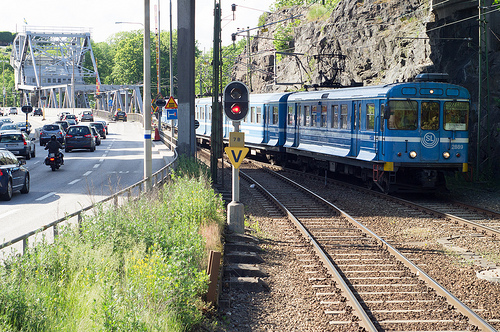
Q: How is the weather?
A: It is clear.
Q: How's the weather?
A: It is clear.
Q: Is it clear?
A: Yes, it is clear.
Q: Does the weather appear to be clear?
A: Yes, it is clear.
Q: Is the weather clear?
A: Yes, it is clear.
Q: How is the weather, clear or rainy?
A: It is clear.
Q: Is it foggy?
A: No, it is clear.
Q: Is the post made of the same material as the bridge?
A: No, the post is made of wood and the bridge is made of metal.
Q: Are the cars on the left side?
A: Yes, the cars are on the left of the image.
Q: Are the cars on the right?
A: No, the cars are on the left of the image.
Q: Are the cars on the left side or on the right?
A: The cars are on the left of the image.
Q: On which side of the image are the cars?
A: The cars are on the left of the image.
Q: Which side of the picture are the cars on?
A: The cars are on the left of the image.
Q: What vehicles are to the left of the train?
A: The vehicles are cars.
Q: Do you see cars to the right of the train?
A: No, the cars are to the left of the train.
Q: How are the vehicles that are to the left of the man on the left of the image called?
A: The vehicles are cars.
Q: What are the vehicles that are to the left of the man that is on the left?
A: The vehicles are cars.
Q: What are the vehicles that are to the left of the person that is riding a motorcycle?
A: The vehicles are cars.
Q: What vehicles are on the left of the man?
A: The vehicles are cars.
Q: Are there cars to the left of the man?
A: Yes, there are cars to the left of the man.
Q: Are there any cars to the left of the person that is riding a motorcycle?
A: Yes, there are cars to the left of the man.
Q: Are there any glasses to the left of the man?
A: No, there are cars to the left of the man.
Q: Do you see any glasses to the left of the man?
A: No, there are cars to the left of the man.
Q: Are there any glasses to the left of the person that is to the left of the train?
A: No, there are cars to the left of the man.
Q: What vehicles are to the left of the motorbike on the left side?
A: The vehicles are cars.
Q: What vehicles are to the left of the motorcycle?
A: The vehicles are cars.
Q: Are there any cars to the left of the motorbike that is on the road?
A: Yes, there are cars to the left of the motorbike.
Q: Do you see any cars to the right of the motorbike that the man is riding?
A: No, the cars are to the left of the motorbike.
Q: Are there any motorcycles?
A: Yes, there is a motorcycle.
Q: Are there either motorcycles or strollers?
A: Yes, there is a motorcycle.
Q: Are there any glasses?
A: No, there are no glasses.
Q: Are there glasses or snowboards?
A: No, there are no glasses or snowboards.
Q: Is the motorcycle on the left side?
A: Yes, the motorcycle is on the left of the image.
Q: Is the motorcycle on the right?
A: No, the motorcycle is on the left of the image.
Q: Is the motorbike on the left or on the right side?
A: The motorbike is on the left of the image.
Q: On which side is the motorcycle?
A: The motorcycle is on the left of the image.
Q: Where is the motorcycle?
A: The motorcycle is on the road.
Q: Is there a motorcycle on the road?
A: Yes, there is a motorcycle on the road.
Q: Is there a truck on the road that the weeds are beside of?
A: No, there is a motorcycle on the road.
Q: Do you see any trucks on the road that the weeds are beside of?
A: No, there is a motorcycle on the road.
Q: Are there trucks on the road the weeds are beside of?
A: No, there is a motorcycle on the road.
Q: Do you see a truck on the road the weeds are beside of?
A: No, there is a motorcycle on the road.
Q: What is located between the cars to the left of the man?
A: The motorbike is between the cars.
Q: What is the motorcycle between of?
A: The motorcycle is between the cars.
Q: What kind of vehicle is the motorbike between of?
A: The motorbike is between the cars.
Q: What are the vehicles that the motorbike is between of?
A: The vehicles are cars.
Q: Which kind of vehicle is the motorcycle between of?
A: The motorbike is between the cars.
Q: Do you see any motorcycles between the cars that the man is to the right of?
A: Yes, there is a motorcycle between the cars.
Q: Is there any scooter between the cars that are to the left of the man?
A: No, there is a motorcycle between the cars.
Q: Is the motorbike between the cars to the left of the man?
A: Yes, the motorbike is between the cars.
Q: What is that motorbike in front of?
A: The motorbike is in front of the car.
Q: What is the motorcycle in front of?
A: The motorbike is in front of the car.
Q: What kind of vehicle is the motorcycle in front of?
A: The motorcycle is in front of the car.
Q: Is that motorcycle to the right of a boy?
A: No, the motorcycle is to the right of the car.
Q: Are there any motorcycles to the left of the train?
A: Yes, there is a motorcycle to the left of the train.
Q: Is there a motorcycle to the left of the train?
A: Yes, there is a motorcycle to the left of the train.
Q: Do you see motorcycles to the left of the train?
A: Yes, there is a motorcycle to the left of the train.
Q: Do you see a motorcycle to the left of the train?
A: Yes, there is a motorcycle to the left of the train.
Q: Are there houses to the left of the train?
A: No, there is a motorcycle to the left of the train.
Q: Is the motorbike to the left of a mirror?
A: No, the motorbike is to the left of the train.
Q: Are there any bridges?
A: Yes, there is a bridge.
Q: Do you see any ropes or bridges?
A: Yes, there is a bridge.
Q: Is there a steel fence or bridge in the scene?
A: Yes, there is a steel bridge.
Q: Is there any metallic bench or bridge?
A: Yes, there is a metal bridge.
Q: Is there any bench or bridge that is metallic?
A: Yes, the bridge is metallic.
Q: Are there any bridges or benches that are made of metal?
A: Yes, the bridge is made of metal.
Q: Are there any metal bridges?
A: Yes, there is a metal bridge.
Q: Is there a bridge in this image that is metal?
A: Yes, there is a metal bridge.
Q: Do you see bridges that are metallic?
A: Yes, there is a bridge that is metallic.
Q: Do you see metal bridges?
A: Yes, there is a bridge that is made of metal.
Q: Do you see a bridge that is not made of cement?
A: Yes, there is a bridge that is made of metal.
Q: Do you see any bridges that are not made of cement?
A: Yes, there is a bridge that is made of metal.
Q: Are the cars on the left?
A: Yes, the cars are on the left of the image.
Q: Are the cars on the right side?
A: No, the cars are on the left of the image.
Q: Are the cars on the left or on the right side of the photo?
A: The cars are on the left of the image.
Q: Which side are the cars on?
A: The cars are on the left of the image.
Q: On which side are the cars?
A: The cars are on the left of the image.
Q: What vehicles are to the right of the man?
A: The vehicles are cars.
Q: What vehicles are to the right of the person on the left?
A: The vehicles are cars.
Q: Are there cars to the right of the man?
A: Yes, there are cars to the right of the man.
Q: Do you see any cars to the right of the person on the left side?
A: Yes, there are cars to the right of the man.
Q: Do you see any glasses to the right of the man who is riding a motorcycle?
A: No, there are cars to the right of the man.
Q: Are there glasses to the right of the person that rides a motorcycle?
A: No, there are cars to the right of the man.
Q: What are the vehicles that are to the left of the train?
A: The vehicles are cars.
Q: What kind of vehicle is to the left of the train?
A: The vehicles are cars.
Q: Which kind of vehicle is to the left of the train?
A: The vehicles are cars.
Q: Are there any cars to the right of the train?
A: No, the cars are to the left of the train.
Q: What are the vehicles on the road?
A: The vehicles are cars.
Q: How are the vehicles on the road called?
A: The vehicles are cars.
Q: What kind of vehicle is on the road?
A: The vehicles are cars.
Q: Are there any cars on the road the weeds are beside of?
A: Yes, there are cars on the road.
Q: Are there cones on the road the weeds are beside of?
A: No, there are cars on the road.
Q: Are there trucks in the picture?
A: No, there are no trucks.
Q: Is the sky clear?
A: Yes, the sky is clear.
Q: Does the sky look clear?
A: Yes, the sky is clear.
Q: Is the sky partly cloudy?
A: No, the sky is clear.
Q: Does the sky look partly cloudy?
A: No, the sky is clear.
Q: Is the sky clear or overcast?
A: The sky is clear.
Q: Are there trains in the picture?
A: Yes, there is a train.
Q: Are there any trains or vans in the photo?
A: Yes, there is a train.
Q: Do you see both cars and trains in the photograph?
A: Yes, there are both a train and cars.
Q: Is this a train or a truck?
A: This is a train.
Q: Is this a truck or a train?
A: This is a train.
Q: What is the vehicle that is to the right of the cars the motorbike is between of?
A: The vehicle is a train.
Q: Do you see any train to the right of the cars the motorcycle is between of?
A: Yes, there is a train to the right of the cars.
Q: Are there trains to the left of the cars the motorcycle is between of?
A: No, the train is to the right of the cars.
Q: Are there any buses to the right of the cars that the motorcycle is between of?
A: No, there is a train to the right of the cars.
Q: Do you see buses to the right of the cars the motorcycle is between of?
A: No, there is a train to the right of the cars.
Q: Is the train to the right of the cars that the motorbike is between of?
A: Yes, the train is to the right of the cars.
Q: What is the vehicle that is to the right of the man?
A: The vehicle is a train.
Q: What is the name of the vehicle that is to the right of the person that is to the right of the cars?
A: The vehicle is a train.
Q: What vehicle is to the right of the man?
A: The vehicle is a train.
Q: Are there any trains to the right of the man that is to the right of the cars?
A: Yes, there is a train to the right of the man.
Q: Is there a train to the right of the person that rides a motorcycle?
A: Yes, there is a train to the right of the man.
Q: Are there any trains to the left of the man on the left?
A: No, the train is to the right of the man.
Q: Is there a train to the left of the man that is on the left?
A: No, the train is to the right of the man.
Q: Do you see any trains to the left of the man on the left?
A: No, the train is to the right of the man.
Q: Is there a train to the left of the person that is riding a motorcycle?
A: No, the train is to the right of the man.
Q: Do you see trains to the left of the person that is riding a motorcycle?
A: No, the train is to the right of the man.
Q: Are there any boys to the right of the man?
A: No, there is a train to the right of the man.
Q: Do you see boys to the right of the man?
A: No, there is a train to the right of the man.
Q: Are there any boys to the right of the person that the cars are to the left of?
A: No, there is a train to the right of the man.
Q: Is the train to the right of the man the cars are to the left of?
A: Yes, the train is to the right of the man.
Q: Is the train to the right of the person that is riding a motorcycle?
A: Yes, the train is to the right of the man.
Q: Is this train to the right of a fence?
A: No, the train is to the right of the man.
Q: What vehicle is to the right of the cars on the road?
A: The vehicle is a train.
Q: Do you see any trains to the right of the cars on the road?
A: Yes, there is a train to the right of the cars.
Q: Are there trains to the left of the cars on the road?
A: No, the train is to the right of the cars.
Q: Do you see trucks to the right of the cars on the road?
A: No, there is a train to the right of the cars.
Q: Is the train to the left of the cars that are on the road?
A: No, the train is to the right of the cars.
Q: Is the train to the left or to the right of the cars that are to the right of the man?
A: The train is to the right of the cars.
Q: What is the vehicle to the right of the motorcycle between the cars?
A: The vehicle is a train.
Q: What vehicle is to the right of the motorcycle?
A: The vehicle is a train.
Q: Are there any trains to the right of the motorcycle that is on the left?
A: Yes, there is a train to the right of the motorbike.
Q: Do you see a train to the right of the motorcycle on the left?
A: Yes, there is a train to the right of the motorbike.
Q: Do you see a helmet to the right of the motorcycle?
A: No, there is a train to the right of the motorcycle.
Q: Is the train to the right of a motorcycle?
A: Yes, the train is to the right of a motorcycle.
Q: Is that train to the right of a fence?
A: No, the train is to the right of a motorcycle.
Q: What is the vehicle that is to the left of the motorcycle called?
A: The vehicle is a car.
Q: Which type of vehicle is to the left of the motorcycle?
A: The vehicle is a car.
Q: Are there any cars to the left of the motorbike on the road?
A: Yes, there is a car to the left of the motorbike.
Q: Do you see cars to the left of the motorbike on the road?
A: Yes, there is a car to the left of the motorbike.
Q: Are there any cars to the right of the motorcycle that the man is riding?
A: No, the car is to the left of the motorbike.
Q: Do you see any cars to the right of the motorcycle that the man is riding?
A: No, the car is to the left of the motorbike.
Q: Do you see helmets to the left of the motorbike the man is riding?
A: No, there is a car to the left of the motorcycle.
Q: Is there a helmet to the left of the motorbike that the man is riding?
A: No, there is a car to the left of the motorcycle.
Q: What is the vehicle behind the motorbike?
A: The vehicle is a car.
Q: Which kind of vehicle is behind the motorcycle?
A: The vehicle is a car.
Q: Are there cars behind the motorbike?
A: Yes, there is a car behind the motorbike.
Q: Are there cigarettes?
A: No, there are no cigarettes.